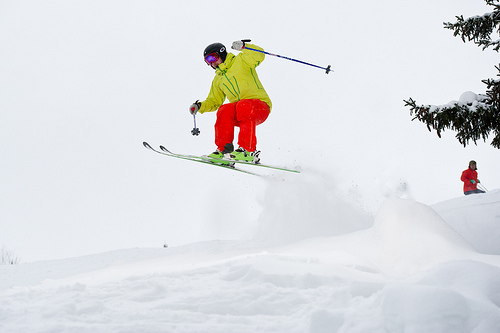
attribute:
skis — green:
[142, 135, 299, 181]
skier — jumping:
[144, 41, 333, 180]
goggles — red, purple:
[205, 53, 224, 65]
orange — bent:
[213, 98, 271, 160]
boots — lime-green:
[205, 148, 263, 167]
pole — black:
[239, 41, 337, 79]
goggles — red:
[199, 48, 226, 66]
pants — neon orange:
[208, 95, 277, 155]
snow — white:
[1, 184, 497, 331]